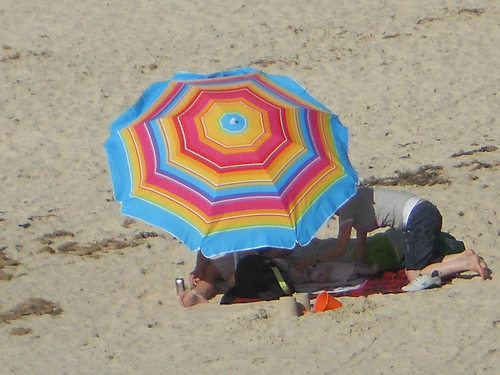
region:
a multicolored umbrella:
[93, 48, 369, 251]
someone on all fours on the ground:
[307, 172, 493, 317]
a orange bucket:
[312, 287, 344, 317]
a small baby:
[291, 242, 372, 281]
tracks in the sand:
[116, 327, 384, 362]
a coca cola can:
[158, 272, 190, 306]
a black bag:
[183, 257, 292, 311]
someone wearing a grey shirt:
[326, 163, 432, 228]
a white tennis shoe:
[391, 257, 456, 296]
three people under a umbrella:
[153, 117, 450, 308]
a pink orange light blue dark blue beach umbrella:
[105, 71, 360, 250]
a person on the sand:
[178, 242, 283, 309]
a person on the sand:
[304, 178, 499, 299]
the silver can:
[175, 275, 186, 292]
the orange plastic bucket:
[315, 289, 340, 307]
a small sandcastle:
[280, 294, 295, 318]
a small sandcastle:
[295, 291, 307, 309]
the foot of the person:
[467, 255, 487, 277]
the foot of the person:
[462, 246, 471, 262]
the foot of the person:
[178, 290, 200, 307]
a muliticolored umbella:
[92, 42, 387, 265]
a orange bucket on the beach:
[304, 283, 347, 322]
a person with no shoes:
[366, 180, 486, 308]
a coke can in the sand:
[170, 268, 197, 301]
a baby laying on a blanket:
[273, 242, 380, 284]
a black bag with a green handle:
[203, 255, 298, 329]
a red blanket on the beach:
[311, 238, 435, 314]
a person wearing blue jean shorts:
[401, 195, 481, 294]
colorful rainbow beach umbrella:
[109, 80, 343, 235]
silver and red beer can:
[171, 274, 193, 302]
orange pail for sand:
[306, 290, 345, 316]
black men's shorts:
[394, 197, 444, 256]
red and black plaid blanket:
[387, 270, 415, 296]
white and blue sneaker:
[398, 260, 444, 298]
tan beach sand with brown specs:
[101, 290, 166, 338]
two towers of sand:
[265, 291, 318, 318]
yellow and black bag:
[241, 255, 305, 311]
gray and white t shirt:
[338, 198, 401, 226]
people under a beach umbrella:
[78, 51, 481, 355]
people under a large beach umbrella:
[74, 52, 484, 345]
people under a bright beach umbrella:
[58, 52, 482, 330]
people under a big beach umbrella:
[78, 31, 487, 351]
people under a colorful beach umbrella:
[86, 60, 477, 356]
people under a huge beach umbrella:
[40, 38, 482, 357]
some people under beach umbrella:
[51, 20, 483, 353]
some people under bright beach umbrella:
[76, 35, 485, 335]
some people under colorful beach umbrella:
[77, 57, 476, 356]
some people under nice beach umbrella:
[85, 45, 483, 338]